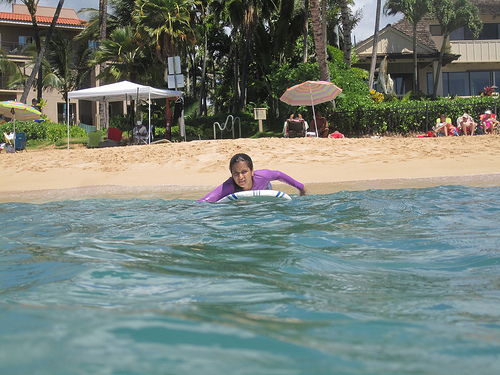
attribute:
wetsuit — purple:
[197, 163, 303, 194]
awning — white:
[66, 82, 186, 105]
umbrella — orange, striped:
[1, 92, 28, 126]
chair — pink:
[287, 118, 305, 132]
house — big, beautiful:
[346, 4, 492, 105]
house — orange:
[3, 7, 126, 128]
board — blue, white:
[220, 187, 290, 207]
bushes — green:
[331, 101, 494, 140]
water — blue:
[11, 209, 488, 369]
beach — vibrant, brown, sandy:
[19, 136, 490, 191]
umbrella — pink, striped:
[273, 77, 329, 136]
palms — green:
[97, 16, 337, 144]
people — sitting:
[279, 114, 496, 148]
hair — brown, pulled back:
[226, 150, 251, 162]